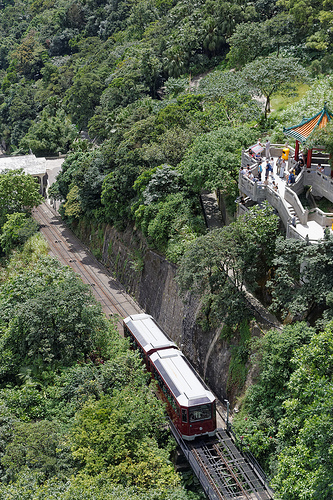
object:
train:
[123, 313, 217, 441]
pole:
[226, 402, 229, 430]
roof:
[285, 102, 331, 140]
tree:
[240, 55, 309, 116]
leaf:
[294, 91, 302, 97]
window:
[182, 410, 188, 423]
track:
[34, 201, 248, 500]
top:
[154, 350, 220, 412]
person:
[258, 162, 264, 179]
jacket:
[280, 161, 285, 168]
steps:
[281, 195, 307, 226]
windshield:
[189, 407, 211, 421]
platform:
[237, 141, 303, 203]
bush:
[163, 226, 196, 263]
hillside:
[0, 2, 332, 324]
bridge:
[175, 430, 271, 500]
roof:
[123, 311, 179, 350]